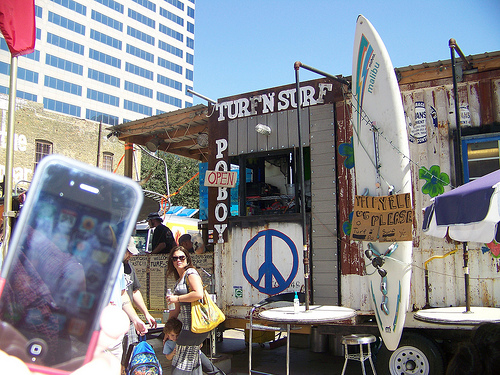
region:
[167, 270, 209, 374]
Woman wearing a dress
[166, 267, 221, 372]
Woman is wearing a dress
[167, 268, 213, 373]
Woman wearing a gray and white dress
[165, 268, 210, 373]
Woman is wearing a gray and white dress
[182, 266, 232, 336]
Woman holding a purse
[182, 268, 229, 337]
Woman is holding a purse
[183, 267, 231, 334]
Woman holding a yellow purse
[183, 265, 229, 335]
Woman is holding a yellow purse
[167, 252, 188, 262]
Woman wearing sunglasses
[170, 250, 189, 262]
Woman is wearing sunglasses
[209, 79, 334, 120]
a sign for TURFN SURF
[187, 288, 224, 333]
a woman with a yellow bag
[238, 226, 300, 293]
a blue peace symbol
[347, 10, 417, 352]
a white and green surfboard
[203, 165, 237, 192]
an open sign on a store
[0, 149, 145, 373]
a person holding an iPhone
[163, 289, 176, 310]
a woman with a plastic bottle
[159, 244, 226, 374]
a woman and a child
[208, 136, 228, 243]
the word POBOY on a sign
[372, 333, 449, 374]
a car tire on the floor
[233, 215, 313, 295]
blue peace sign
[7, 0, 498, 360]
surf shop with surf boards hanging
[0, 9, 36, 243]
pole with a red flag hanging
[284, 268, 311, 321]
blue bottle sitting on table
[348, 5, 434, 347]
white surf board hanging up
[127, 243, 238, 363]
woman and child outside of surf shop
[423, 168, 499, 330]
navy blue and white umbrella on table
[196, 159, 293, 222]
open sign for surf shop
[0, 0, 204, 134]
a building with lots of windows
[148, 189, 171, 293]
man wearing a hat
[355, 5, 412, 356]
Blue and white sail board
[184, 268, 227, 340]
Yellow bag on womans shoulder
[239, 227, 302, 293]
Blue peace sign on white background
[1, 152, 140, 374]
Reflection in a cell phone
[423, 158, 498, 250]
Purple and white umrella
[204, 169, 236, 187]
White sign with red letters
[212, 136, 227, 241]
Black sign with white letters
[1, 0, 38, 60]
Part of red flag on pole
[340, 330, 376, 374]
Silver stool with four legs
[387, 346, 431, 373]
White tire rim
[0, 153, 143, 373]
cell phone in the foreground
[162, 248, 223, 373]
young woman with a yellow handbag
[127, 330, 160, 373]
blue backpack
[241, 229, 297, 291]
blue painted peace sign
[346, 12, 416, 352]
surfboard with a cardboard sign attached to it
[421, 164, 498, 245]
white and purple patio umbrella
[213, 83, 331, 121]
sign for Turf N Surf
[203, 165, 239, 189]
OPEN sign with red letters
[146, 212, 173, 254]
man wearing a hat and a black t-shirt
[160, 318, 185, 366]
child clinging to a woman